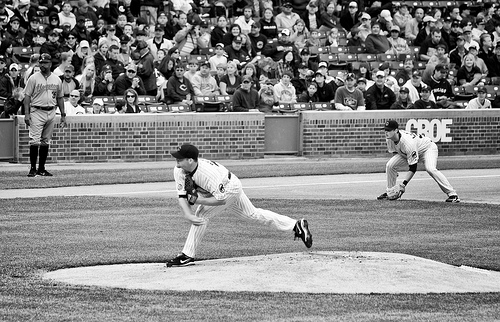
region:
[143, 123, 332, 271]
player on pitcher's mound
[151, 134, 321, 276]
pitcher pitching the ball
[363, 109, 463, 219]
player at third base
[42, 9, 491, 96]
spectators sitting in the stands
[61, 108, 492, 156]
brick wall around field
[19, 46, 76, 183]
coach standing on side of field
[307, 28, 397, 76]
empty seats in stands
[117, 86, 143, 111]
woman wearing sun glasses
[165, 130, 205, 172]
man wearing baseball cap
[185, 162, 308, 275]
white suit with pinstripes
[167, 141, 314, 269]
A baseball player threw a ball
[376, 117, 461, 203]
A baseball player is poised and waiting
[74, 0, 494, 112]
An audience watches a baseball game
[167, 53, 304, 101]
Parents and children in the bleachers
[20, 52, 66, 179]
A baseball player stands on the outer edge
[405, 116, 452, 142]
an acronym on a wall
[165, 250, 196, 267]
baseball player wearing Nike brand shoes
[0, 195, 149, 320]
freshly manicured grass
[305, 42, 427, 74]
A few empty seats in baseball field bleachers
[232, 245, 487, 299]
a baseball mound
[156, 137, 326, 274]
baseball pitcher throwing a ball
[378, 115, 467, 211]
baseball player wearing a mitt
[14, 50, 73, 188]
baseball player wearing a black helmet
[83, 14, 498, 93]
crowd of people watching baseball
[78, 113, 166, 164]
a wall with rectangular bricks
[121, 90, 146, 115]
a woman wearing sunglasses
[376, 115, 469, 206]
baseball player crouching down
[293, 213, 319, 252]
a black and white sneaker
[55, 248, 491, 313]
A pitcher's mound on a baseball field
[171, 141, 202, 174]
A man wearing a black baseball hat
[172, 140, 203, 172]
the head of a man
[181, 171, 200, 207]
a baseball mitt on the man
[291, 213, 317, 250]
a black shoe on the man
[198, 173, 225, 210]
the arm of the man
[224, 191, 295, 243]
the leg of the man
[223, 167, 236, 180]
a belt on the man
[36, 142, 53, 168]
a tall black sock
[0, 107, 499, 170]
a brick wall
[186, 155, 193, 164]
the ear of the man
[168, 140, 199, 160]
a baseball cap on the man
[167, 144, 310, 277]
Pitcher is bent over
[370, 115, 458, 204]
Baseman is bent over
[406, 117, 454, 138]
CROE is written in white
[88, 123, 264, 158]
Wall is made of brick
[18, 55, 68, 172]
Opposing teammate is standing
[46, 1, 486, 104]
Stadium is full of spectators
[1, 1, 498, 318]
Picture is taken in black and white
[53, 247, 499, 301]
Diamond is landscaped nicely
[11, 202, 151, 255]
Grass is cut short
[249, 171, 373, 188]
White chalk line on field